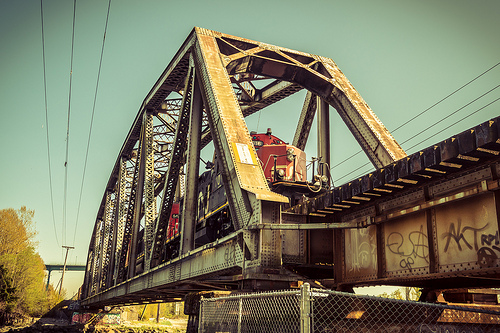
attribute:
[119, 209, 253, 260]
bridge — tall, yellow, old, crossing, large, background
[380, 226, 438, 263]
words — black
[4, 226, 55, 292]
trees — green, tall, grouped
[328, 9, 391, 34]
sky — clear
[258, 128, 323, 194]
train — red, old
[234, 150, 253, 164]
paper — white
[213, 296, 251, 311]
fence — wire, chain link, chain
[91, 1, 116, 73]
wire — hanging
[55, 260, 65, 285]
pole — tall, large